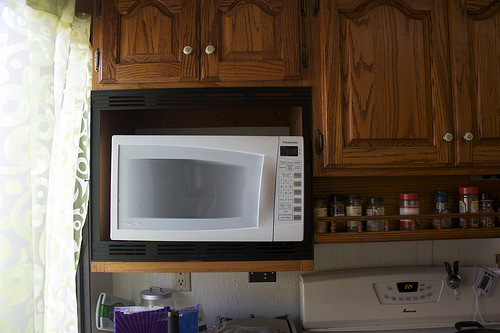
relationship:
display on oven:
[278, 144, 303, 225] [109, 124, 304, 243]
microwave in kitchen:
[75, 114, 359, 280] [7, 7, 499, 327]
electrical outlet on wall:
[147, 265, 219, 313] [86, 42, 471, 317]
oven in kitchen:
[301, 266, 498, 328] [7, 7, 499, 327]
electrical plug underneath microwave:
[169, 270, 193, 292] [75, 114, 359, 280]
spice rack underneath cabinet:
[312, 185, 498, 242] [306, 8, 497, 169]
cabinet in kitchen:
[311, 0, 499, 173] [7, 7, 499, 327]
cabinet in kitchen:
[91, 0, 310, 91] [7, 7, 499, 327]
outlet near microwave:
[171, 271, 194, 293] [75, 114, 359, 280]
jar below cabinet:
[397, 188, 423, 233] [322, 27, 498, 167]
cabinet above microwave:
[91, 0, 310, 91] [75, 114, 359, 280]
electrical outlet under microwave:
[147, 265, 219, 313] [75, 114, 359, 280]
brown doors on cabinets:
[96, 2, 305, 82] [91, 0, 308, 91]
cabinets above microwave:
[118, 17, 293, 67] [75, 114, 359, 280]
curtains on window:
[1, 2, 92, 332] [0, 0, 93, 329]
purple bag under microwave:
[108, 299, 174, 331] [75, 114, 359, 280]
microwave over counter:
[36, 57, 356, 250] [97, 79, 447, 292]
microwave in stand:
[36, 57, 356, 250] [89, 90, 314, 272]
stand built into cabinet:
[89, 90, 314, 272] [89, 84, 314, 272]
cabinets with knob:
[90, 0, 498, 175] [442, 130, 455, 142]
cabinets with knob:
[90, 0, 498, 175] [204, 45, 215, 54]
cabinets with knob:
[90, 0, 498, 175] [183, 45, 193, 54]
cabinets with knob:
[90, 0, 498, 175] [464, 131, 473, 140]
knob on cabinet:
[442, 130, 455, 142] [320, 27, 462, 169]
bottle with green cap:
[434, 189, 449, 224] [432, 186, 447, 199]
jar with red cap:
[397, 188, 423, 233] [456, 185, 479, 195]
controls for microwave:
[277, 160, 305, 222] [75, 114, 359, 280]